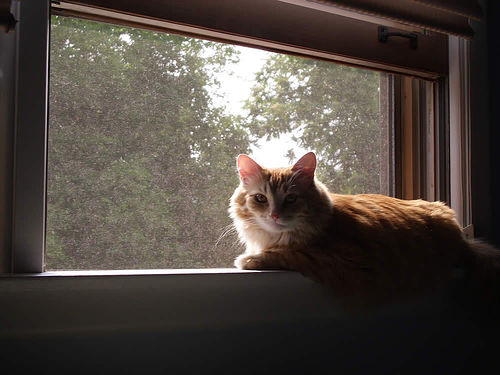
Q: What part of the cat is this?
A: The body.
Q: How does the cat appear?
A: Orange and white.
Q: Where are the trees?
A: Outside the window.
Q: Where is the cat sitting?
A: In the window sill.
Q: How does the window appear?
A: Wide.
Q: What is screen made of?
A: Mesh.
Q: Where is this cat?
A: Sitting on windowsill.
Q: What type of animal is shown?
A: Cat.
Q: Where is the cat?
A: Window sill.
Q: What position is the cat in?
A: Lying.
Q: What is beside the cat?
A: Window screen.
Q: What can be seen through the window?
A: Trees and sky.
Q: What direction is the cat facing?
A: Left.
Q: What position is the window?
A: Open.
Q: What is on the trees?
A: Leaves.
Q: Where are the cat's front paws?
A: In front of the cat.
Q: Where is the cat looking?
A: At the camera.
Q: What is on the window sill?
A: A cat.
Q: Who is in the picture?
A: No one.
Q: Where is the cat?
A: On the window sill.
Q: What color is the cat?
A: Orange.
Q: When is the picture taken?
A: Daytime.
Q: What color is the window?
A: White.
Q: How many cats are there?
A: 1.